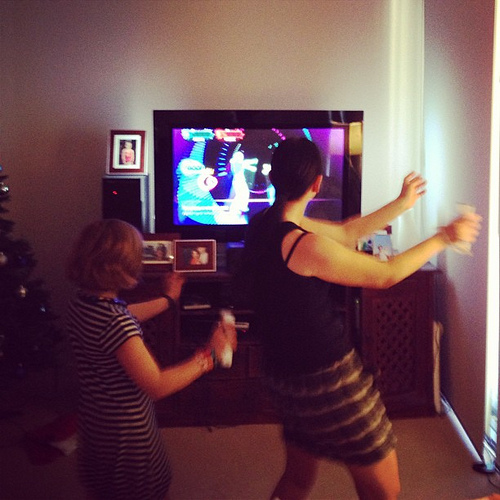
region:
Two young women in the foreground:
[53, 107, 486, 499]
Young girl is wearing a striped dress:
[58, 287, 183, 498]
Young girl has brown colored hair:
[60, 214, 154, 296]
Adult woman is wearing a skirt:
[255, 350, 409, 475]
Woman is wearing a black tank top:
[228, 216, 365, 387]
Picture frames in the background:
[92, 117, 221, 284]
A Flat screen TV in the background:
[147, 101, 374, 243]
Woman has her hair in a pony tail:
[232, 133, 337, 286]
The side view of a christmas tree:
[1, 157, 64, 433]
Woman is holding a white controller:
[432, 197, 490, 269]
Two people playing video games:
[68, 139, 482, 499]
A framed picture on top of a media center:
[173, 238, 216, 270]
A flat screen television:
[153, 109, 361, 239]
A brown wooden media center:
[117, 255, 438, 425]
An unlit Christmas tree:
[0, 165, 64, 404]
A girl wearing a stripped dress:
[65, 219, 236, 499]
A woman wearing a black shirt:
[243, 138, 480, 373]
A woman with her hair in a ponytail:
[230, 135, 321, 290]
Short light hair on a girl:
[62, 217, 143, 292]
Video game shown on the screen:
[171, 126, 346, 227]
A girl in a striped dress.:
[61, 210, 231, 498]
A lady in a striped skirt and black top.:
[243, 118, 478, 498]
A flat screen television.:
[153, 107, 360, 242]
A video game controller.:
[218, 310, 233, 368]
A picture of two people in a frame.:
[172, 240, 217, 270]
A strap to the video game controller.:
[439, 220, 461, 255]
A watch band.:
[163, 292, 178, 312]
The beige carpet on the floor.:
[178, 435, 243, 491]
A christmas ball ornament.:
[0, 181, 10, 198]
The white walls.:
[144, 24, 319, 81]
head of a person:
[245, 129, 336, 230]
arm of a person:
[313, 182, 407, 252]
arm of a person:
[342, 222, 457, 303]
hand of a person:
[437, 206, 481, 268]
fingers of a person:
[403, 169, 445, 213]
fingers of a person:
[447, 219, 479, 254]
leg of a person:
[346, 373, 393, 490]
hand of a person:
[202, 303, 243, 363]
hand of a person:
[156, 255, 218, 302]